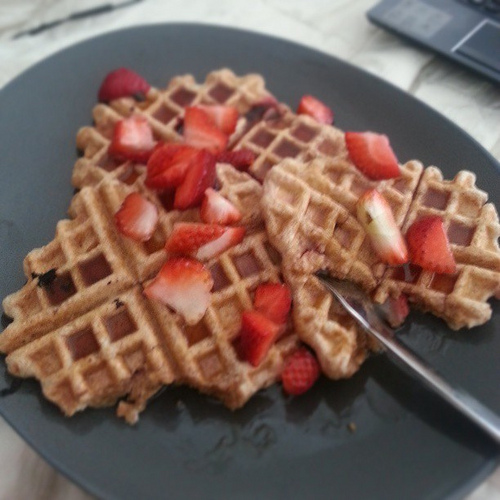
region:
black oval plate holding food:
[0, 13, 498, 498]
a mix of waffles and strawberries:
[6, 61, 499, 425]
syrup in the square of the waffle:
[62, 322, 100, 359]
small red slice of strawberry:
[283, 344, 320, 391]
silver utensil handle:
[376, 333, 498, 457]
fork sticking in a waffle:
[303, 247, 498, 449]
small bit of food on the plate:
[344, 419, 357, 435]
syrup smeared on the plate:
[204, 417, 296, 462]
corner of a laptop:
[361, 0, 499, 67]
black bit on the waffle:
[32, 266, 60, 286]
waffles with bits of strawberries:
[3, 64, 498, 421]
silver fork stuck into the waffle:
[312, 256, 498, 457]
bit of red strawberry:
[275, 341, 316, 398]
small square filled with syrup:
[63, 328, 101, 358]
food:
[1, 49, 472, 433]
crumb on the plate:
[343, 421, 358, 438]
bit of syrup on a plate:
[205, 424, 285, 466]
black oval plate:
[3, 17, 495, 499]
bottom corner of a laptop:
[368, 2, 497, 78]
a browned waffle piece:
[7, 182, 302, 418]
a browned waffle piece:
[258, 127, 495, 334]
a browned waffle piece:
[73, 62, 337, 196]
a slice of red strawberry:
[143, 253, 213, 323]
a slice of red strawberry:
[230, 310, 282, 362]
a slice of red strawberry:
[273, 344, 315, 393]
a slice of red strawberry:
[354, 185, 406, 266]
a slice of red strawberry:
[402, 214, 466, 273]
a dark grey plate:
[0, 19, 493, 497]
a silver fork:
[312, 266, 498, 456]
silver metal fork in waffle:
[319, 269, 498, 456]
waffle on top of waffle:
[260, 150, 498, 381]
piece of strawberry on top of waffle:
[407, 214, 457, 274]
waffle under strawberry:
[264, 156, 497, 376]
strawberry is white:
[355, 187, 405, 267]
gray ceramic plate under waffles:
[0, 22, 499, 499]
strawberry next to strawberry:
[240, 312, 278, 364]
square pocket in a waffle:
[27, 344, 62, 376]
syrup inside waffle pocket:
[101, 310, 136, 340]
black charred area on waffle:
[30, 265, 62, 289]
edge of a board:
[415, 102, 428, 119]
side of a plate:
[305, 485, 312, 492]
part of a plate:
[212, 396, 214, 445]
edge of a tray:
[57, 443, 97, 455]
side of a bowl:
[156, 466, 169, 483]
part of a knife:
[426, 380, 434, 397]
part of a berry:
[282, 357, 289, 372]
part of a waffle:
[92, 347, 104, 372]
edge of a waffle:
[146, 365, 161, 380]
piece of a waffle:
[218, 348, 260, 408]